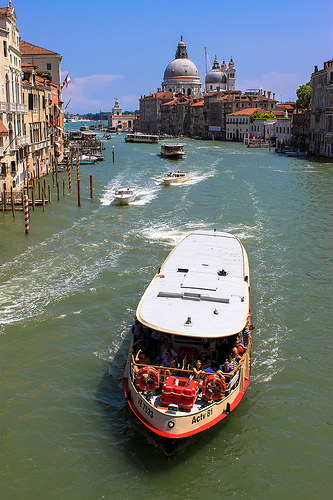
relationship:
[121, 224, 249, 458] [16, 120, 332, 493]
boat on top of water